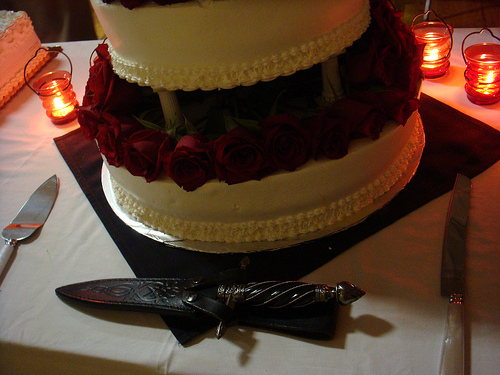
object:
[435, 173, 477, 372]
pie cutter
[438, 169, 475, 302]
blade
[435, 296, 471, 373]
handle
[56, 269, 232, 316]
sheath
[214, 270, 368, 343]
knife handle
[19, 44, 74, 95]
candle handle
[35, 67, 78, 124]
candle holder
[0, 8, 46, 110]
cake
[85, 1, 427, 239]
cake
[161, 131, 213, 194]
rose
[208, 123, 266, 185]
rose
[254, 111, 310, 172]
rose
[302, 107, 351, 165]
rose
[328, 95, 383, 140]
rose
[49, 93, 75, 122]
candle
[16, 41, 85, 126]
jar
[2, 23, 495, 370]
tablecloth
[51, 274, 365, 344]
knife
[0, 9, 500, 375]
table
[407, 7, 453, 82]
candle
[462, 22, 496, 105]
candle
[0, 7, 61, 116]
edge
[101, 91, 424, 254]
bottom layer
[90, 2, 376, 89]
top layer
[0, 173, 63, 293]
serving knife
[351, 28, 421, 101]
roses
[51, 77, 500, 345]
case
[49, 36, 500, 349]
napkin